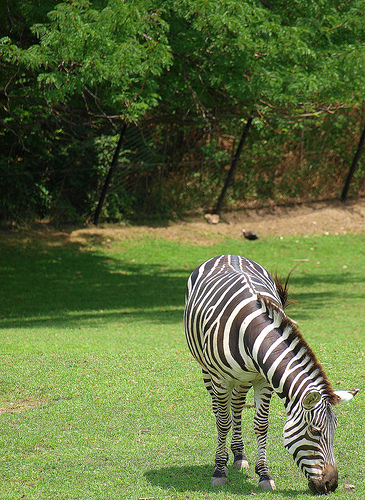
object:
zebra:
[182, 251, 362, 500]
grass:
[1, 230, 365, 499]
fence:
[0, 104, 365, 232]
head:
[280, 387, 362, 496]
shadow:
[141, 460, 310, 497]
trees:
[61, 41, 72, 81]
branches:
[101, 112, 107, 125]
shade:
[1, 216, 364, 330]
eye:
[308, 424, 323, 437]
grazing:
[276, 450, 364, 499]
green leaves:
[64, 29, 70, 34]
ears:
[301, 388, 321, 411]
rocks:
[204, 212, 220, 224]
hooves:
[255, 465, 277, 493]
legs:
[252, 382, 277, 492]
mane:
[256, 290, 339, 408]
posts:
[92, 119, 130, 230]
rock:
[242, 228, 259, 240]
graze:
[299, 456, 343, 499]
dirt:
[38, 194, 365, 240]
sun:
[22, 0, 365, 106]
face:
[281, 402, 339, 494]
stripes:
[220, 289, 230, 296]